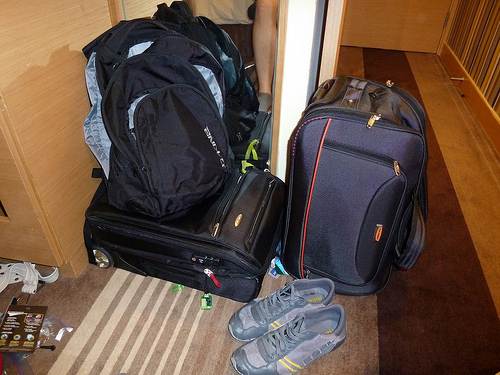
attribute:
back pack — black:
[79, 19, 235, 224]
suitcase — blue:
[272, 73, 431, 304]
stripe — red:
[294, 119, 335, 283]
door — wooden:
[342, 7, 446, 57]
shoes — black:
[206, 242, 384, 374]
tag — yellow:
[240, 135, 265, 164]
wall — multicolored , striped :
[456, 2, 497, 59]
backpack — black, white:
[276, 69, 435, 321]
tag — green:
[197, 290, 219, 311]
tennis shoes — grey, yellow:
[223, 269, 353, 373]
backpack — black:
[91, 26, 267, 188]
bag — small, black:
[81, 152, 293, 304]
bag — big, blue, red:
[269, 69, 442, 306]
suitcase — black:
[87, 177, 283, 302]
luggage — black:
[261, 41, 436, 280]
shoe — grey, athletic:
[217, 262, 357, 374]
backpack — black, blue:
[84, 17, 236, 223]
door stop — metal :
[445, 65, 467, 85]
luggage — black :
[64, 144, 294, 311]